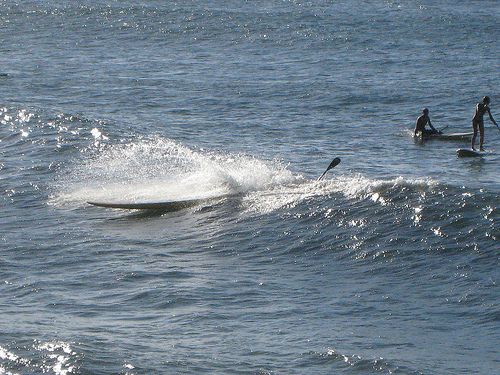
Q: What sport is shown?
A: Paddle boarding.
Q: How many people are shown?
A: Two.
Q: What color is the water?
A: Blue.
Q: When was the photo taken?
A: Daytime.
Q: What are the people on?
A: Boards.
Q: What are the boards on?
A: Water.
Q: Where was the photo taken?
A: Ocean.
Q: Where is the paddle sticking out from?
A: Wave.